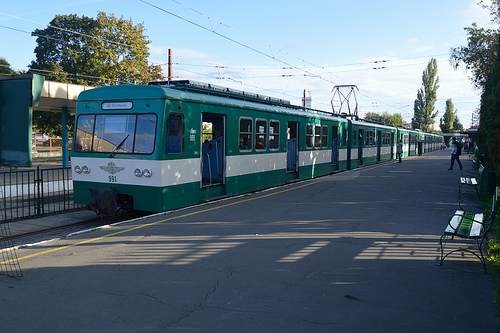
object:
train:
[69, 82, 446, 213]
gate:
[5, 161, 64, 223]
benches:
[438, 185, 499, 273]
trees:
[409, 57, 441, 133]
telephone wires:
[263, 59, 361, 72]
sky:
[306, 2, 386, 41]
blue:
[332, 5, 388, 35]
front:
[70, 82, 166, 212]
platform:
[179, 180, 400, 273]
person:
[447, 135, 464, 171]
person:
[395, 139, 404, 163]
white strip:
[70, 156, 165, 187]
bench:
[458, 163, 486, 198]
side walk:
[288, 190, 401, 242]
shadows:
[191, 219, 411, 285]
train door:
[197, 110, 227, 188]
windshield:
[74, 113, 159, 153]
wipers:
[104, 134, 132, 155]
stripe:
[142, 213, 187, 228]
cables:
[362, 63, 415, 71]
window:
[165, 111, 185, 156]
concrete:
[418, 180, 447, 211]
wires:
[282, 53, 323, 82]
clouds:
[458, 2, 491, 17]